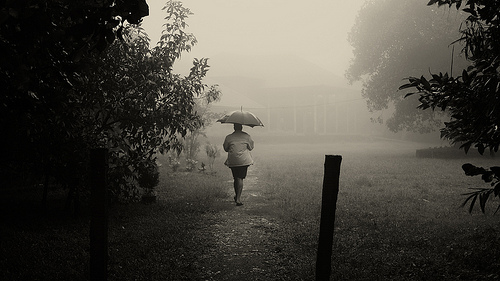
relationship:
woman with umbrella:
[223, 123, 254, 206] [217, 105, 264, 127]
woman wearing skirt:
[223, 123, 254, 206] [229, 167, 247, 179]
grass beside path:
[257, 141, 500, 281] [207, 146, 273, 279]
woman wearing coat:
[223, 123, 254, 206] [222, 131, 254, 167]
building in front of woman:
[207, 106, 374, 136] [223, 123, 254, 206]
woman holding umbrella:
[223, 123, 254, 206] [217, 105, 264, 127]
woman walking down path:
[223, 123, 254, 206] [207, 146, 273, 279]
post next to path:
[90, 149, 109, 280] [207, 146, 273, 279]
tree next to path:
[26, 0, 222, 201] [207, 146, 273, 279]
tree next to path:
[345, 0, 475, 146] [207, 146, 273, 279]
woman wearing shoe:
[223, 123, 254, 206] [237, 202, 243, 207]